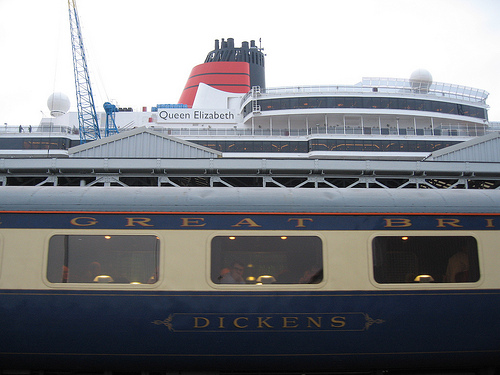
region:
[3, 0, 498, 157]
Cruise ship "Queen Elizabeth"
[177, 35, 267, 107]
Red and black exhaust stacks on ship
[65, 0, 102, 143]
Blue vertical crane boom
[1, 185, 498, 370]
Blue and white train car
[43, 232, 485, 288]
Windows in train car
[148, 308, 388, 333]
Yellow letters on side of train spelling "Dickens"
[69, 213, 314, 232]
Word "Great" painted in yellow letters above windows of train car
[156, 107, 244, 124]
Sign board displaying name of ship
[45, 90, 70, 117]
Round white radar dome on ship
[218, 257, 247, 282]
Passenger looking out of train window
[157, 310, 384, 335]
Yellow letters on side.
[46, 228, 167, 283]
Small window to the left.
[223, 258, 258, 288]
Man looking out the window.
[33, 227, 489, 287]
Three windows on boat.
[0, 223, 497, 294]
White stripe of paint on side.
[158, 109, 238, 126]
Queen Elizabeth written on top.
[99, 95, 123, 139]
Blue ladder at the top.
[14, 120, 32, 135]
Two people on top of boat.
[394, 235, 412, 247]
Light shining from inside.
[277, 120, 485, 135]
Line of windows on the boat.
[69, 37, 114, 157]
the crane is blue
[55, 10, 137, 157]
the crane is blue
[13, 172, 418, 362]
a blue and cream train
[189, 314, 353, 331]
The word dickens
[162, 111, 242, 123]
The name queen elizabeth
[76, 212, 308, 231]
The word great written on the side of the boat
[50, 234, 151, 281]
The window of the boat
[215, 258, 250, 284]
The person in the window of the boat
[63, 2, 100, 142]
A blue crane above the boat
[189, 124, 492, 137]
The railing on the boat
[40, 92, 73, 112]
White circle by the crane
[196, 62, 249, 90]
Red and blue striped part of the boat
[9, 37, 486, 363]
The entire boat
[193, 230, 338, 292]
The people are in the window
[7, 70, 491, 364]
This is a ship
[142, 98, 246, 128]
The sign says Queen Elizabeth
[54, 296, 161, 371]
The bottom of the boat is blue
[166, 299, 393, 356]
The boat says Dickens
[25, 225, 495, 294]
The boat has 3 windows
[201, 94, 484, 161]
The balcony is empty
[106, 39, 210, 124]
The sky is white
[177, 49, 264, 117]
The boat has red on the top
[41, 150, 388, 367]
The boat is red white and blue